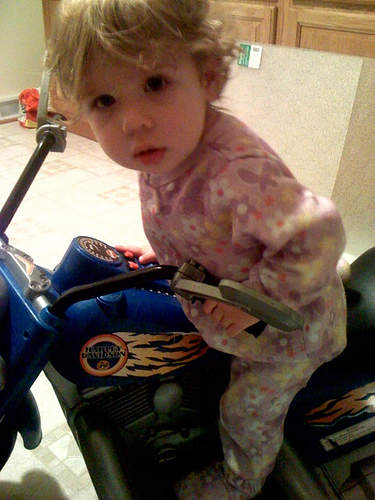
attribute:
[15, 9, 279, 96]
hair — blonde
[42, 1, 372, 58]
cabinet — wooden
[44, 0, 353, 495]
girl — little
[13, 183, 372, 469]
harley — blue, toy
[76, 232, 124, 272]
speedometer — little, pretend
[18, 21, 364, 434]
biker — -in-training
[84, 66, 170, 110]
eyes — big, dark, bambi